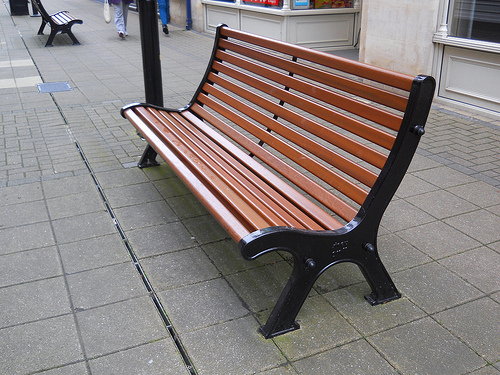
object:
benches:
[29, 0, 84, 48]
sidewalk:
[4, 217, 486, 361]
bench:
[119, 22, 437, 339]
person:
[111, 1, 127, 41]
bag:
[100, 4, 112, 25]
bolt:
[302, 259, 318, 271]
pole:
[136, 0, 162, 107]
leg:
[258, 267, 323, 341]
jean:
[156, 2, 173, 23]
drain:
[35, 80, 70, 94]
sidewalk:
[28, 22, 242, 237]